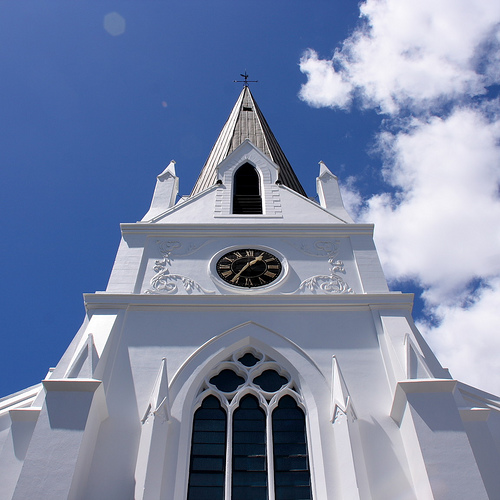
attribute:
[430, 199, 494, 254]
clouds — white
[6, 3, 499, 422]
sky — blue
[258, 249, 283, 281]
numeral — Roman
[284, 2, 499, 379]
clouds — white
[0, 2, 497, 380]
sky — blue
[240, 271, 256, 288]
numeral — roman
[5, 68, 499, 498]
building — tall, white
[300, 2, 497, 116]
clouds — white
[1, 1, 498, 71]
sky — blue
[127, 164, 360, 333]
wall — floral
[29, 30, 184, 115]
sky — blue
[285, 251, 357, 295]
design — floral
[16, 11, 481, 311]
sky — blue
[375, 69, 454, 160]
clouds — white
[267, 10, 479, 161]
sky — blue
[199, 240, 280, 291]
time — 1:35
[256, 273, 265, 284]
five — numeral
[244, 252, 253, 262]
numeral — Roman